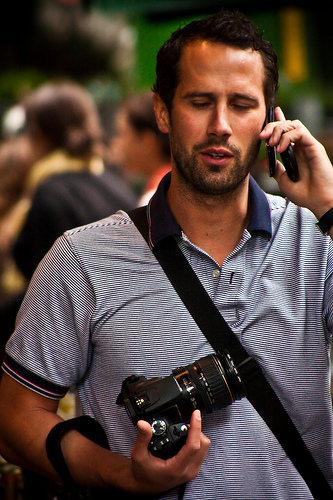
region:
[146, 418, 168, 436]
Black, white, and green camera dial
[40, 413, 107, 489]
Black camera strap around the man's arm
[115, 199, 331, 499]
Black strap across the man's chest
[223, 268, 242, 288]
Hole in the shirt for a button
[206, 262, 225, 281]
White button near the collar of the shirt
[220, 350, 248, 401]
Tip of the camera lens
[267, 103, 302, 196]
Black cellphone next to the man's ear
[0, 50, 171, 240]
Two people standing in the background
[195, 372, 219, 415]
Numbered dial on the camera lens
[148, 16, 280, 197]
THIS IS HIS FACE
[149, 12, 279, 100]
THATS HIS BLACK HAIR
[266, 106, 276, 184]
THIS IS HIS CELL PHONE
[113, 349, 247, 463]
THIS IS HIS CAMERA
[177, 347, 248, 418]
THIS IS THE LENS ON THE CAMERA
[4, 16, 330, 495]
THIS IS A MAN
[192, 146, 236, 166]
THESE ARE HIS LIPS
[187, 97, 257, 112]
THESE ARE HIS EYES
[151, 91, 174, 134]
THESE ARE HIS EARS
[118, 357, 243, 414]
a camera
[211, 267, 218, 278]
a button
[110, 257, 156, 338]
man is wearing a shirt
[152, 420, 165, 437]
button on the camera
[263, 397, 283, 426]
a black strap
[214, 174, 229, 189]
the man has a beard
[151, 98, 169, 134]
right ear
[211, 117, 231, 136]
the mans nose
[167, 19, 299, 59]
Man has dark hair.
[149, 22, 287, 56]
Man has short hair.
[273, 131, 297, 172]
Man holding cell phone.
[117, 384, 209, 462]
Man holding camera in hand.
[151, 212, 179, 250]
Blue collar on man's shirt.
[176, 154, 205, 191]
Man has dark facial hair.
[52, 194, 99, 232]
Person wearing black shirt.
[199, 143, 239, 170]
a camera man's mouth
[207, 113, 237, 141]
a camera man's nose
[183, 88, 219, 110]
a camera man's eyes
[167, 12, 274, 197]
a camera man's head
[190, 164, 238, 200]
a camera man's chin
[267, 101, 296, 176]
a camera man's phone on his ear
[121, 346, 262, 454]
a camera held by a camera man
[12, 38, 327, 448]
a camera man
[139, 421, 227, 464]
the fingers of the camera man